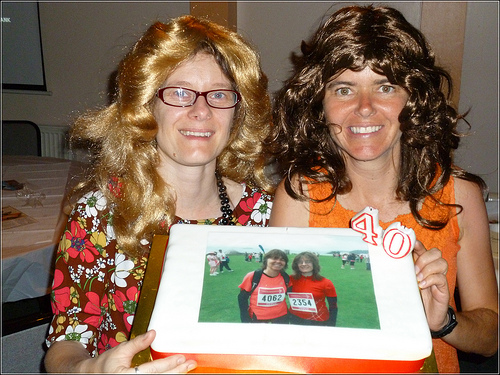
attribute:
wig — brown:
[258, 2, 487, 235]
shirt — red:
[258, 275, 288, 315]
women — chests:
[132, 34, 486, 259]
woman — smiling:
[281, 4, 497, 368]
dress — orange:
[299, 146, 466, 367]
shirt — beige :
[45, 174, 271, 354]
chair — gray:
[34, 65, 153, 162]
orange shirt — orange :
[302, 190, 342, 209]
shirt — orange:
[304, 167, 477, 374]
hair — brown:
[258, 0, 497, 230]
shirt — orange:
[272, 156, 483, 284]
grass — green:
[166, 245, 381, 362]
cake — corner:
[130, 187, 436, 374]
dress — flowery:
[88, 193, 203, 340]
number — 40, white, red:
[349, 200, 420, 262]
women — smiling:
[32, 3, 498, 373]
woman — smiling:
[40, 12, 271, 372]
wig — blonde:
[80, 9, 284, 242]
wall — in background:
[49, 11, 104, 83]